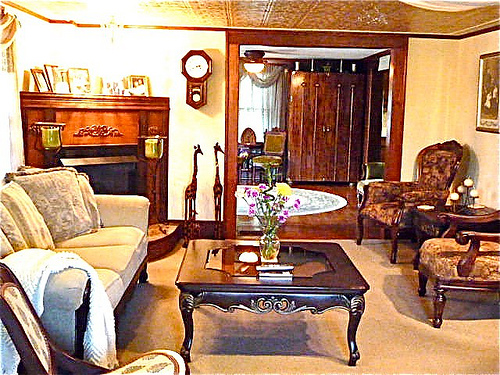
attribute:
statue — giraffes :
[210, 137, 228, 240]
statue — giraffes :
[177, 140, 204, 250]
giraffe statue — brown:
[211, 141, 233, 235]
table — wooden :
[173, 236, 370, 366]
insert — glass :
[203, 245, 335, 278]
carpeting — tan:
[114, 238, 498, 373]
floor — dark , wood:
[135, 214, 483, 374]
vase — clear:
[249, 216, 291, 261]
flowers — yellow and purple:
[262, 163, 360, 231]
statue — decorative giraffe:
[213, 142, 226, 235]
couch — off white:
[2, 157, 158, 370]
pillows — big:
[12, 159, 108, 249]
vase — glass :
[253, 224, 280, 261]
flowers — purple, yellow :
[232, 176, 299, 228]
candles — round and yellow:
[443, 178, 492, 214]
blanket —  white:
[3, 249, 120, 368]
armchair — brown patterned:
[349, 137, 469, 259]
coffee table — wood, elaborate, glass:
[177, 232, 366, 368]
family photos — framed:
[25, 56, 161, 99]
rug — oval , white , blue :
[232, 177, 351, 224]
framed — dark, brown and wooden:
[391, 162, 441, 256]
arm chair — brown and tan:
[369, 173, 418, 263]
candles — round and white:
[232, 220, 254, 300]